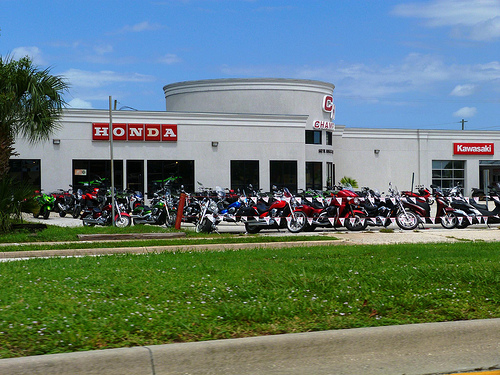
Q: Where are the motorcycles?
A: On the lot.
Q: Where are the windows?
A: On the building.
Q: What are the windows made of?
A: Glass.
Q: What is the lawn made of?
A: Grass.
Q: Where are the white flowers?
A: In the grass.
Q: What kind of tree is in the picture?
A: Palm.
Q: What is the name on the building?
A: Honda.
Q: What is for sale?
A: Motorcycles.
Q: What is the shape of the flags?
A: Triangles.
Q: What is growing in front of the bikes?
A: Grass.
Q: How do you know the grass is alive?
A: It's green.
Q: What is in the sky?
A: Clouds.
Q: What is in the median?
A: Grass.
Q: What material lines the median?
A: Concrete.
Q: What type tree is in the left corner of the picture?
A: Palm Tree.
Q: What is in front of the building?
A: Motorcycles.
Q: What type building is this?
A: Motorcycle dealership.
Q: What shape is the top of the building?
A: Round.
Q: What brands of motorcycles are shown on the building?
A: Honda and Kawasaki.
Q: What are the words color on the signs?
A: White.